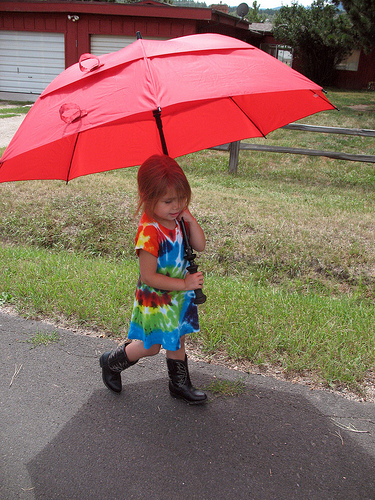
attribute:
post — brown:
[241, 143, 372, 164]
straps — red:
[55, 51, 106, 125]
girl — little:
[87, 146, 220, 410]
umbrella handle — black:
[145, 105, 212, 306]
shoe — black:
[165, 352, 208, 405]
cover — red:
[42, 25, 257, 95]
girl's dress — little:
[130, 213, 202, 351]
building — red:
[1, 0, 374, 107]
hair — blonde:
[128, 153, 167, 198]